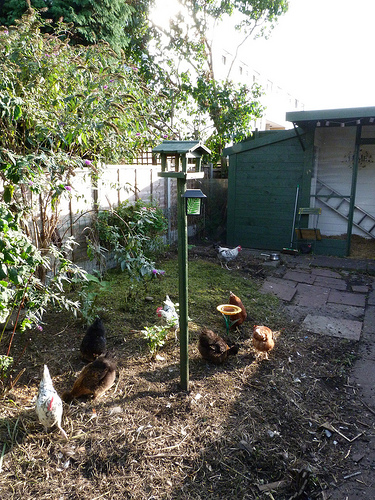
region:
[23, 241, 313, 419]
chickens in a yard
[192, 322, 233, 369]
dark chicken in the yard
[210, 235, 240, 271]
light chicken in the yard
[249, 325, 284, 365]
golden chicken in the yard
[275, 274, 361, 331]
brick on the sidewalk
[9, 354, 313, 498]
mulch area chickens stand in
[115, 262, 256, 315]
grass in the yard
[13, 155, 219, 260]
fence to the side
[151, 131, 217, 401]
feeder for birds on pole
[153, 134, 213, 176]
house like structure on top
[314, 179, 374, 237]
a ladder leaning against the building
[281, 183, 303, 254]
a broom leaning against the building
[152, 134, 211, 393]
a green bird feeder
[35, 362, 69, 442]
a white chicken with black spots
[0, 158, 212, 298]
a fence on the side of the property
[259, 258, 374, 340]
a walkway in disrepair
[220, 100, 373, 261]
a green and white chicken coop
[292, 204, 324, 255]
a folding chair leaning against the building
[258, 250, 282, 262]
a small metal pot on the ground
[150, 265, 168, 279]
purple flowers on the plant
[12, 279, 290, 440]
chickens in the yard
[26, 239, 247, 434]
three white chickens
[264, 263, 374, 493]
stone pathway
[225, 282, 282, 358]
two brown chickens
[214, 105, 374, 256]
green and white shed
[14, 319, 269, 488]
sunlight on the ground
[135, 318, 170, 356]
flower growing in the bare dirt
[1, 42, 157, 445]
tree with purple flowers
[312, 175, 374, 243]
ladder propped on the side of the shed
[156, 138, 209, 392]
birdhouse on a green pole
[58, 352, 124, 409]
brown chicken on ground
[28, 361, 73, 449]
white chicken on ground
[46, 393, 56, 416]
red top of head of white chicken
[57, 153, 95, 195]
lavender flowers on tree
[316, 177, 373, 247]
metal ladder against wall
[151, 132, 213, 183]
bird feeder on green pole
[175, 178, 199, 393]
green bird feeder support pole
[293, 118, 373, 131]
string lights on roof of green house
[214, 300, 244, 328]
yellow feeder on ground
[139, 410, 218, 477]
dirt and straw on ground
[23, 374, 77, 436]
chicken on a field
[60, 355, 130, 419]
chicken on a field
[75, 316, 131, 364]
chicken on a field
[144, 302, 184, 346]
chicken on a field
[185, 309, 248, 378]
chicken on a field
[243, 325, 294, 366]
chicken on a field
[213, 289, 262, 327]
chicken on a field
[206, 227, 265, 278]
chicken on a field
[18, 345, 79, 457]
a chicken on a field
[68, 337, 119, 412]
a chicken on a field